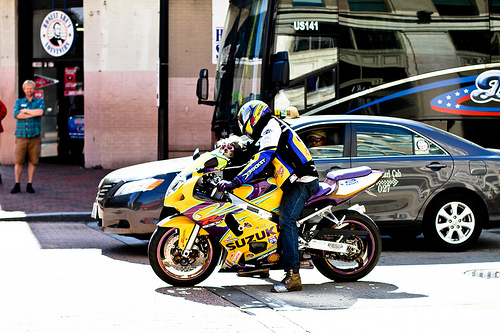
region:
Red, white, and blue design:
[433, 68, 495, 114]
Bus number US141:
[292, 15, 323, 32]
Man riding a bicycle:
[160, 103, 357, 283]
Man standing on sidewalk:
[5, 77, 47, 200]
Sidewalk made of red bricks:
[47, 169, 84, 209]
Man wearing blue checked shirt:
[11, 78, 43, 140]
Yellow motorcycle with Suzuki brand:
[166, 168, 283, 278]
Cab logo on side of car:
[376, 164, 406, 196]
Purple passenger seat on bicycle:
[328, 163, 369, 185]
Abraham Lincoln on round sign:
[37, 10, 73, 62]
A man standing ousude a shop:
[12, 73, 50, 193]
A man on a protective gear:
[225, 112, 305, 278]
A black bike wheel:
[148, 224, 215, 289]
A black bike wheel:
[325, 207, 387, 291]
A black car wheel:
[430, 187, 485, 248]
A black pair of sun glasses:
[306, 135, 328, 143]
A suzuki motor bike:
[170, 166, 395, 297]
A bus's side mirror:
[194, 66, 222, 113]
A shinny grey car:
[309, 110, 499, 242]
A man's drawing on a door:
[38, 9, 81, 59]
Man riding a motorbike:
[144, 98, 384, 290]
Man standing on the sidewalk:
[7, 75, 47, 201]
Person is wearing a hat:
[302, 125, 330, 152]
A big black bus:
[193, 37, 498, 151]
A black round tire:
[421, 188, 485, 254]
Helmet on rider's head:
[233, 95, 273, 140]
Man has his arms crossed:
[11, 76, 46, 141]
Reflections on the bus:
[236, 37, 491, 141]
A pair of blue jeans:
[276, 181, 323, 270]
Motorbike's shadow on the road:
[153, 279, 431, 315]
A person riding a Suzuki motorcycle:
[144, 95, 385, 294]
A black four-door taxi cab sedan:
[88, 112, 499, 254]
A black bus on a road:
[193, 0, 498, 157]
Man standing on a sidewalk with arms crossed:
[9, 78, 46, 197]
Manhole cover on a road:
[460, 263, 499, 284]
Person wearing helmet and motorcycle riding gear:
[215, 98, 320, 295]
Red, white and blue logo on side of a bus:
[428, 66, 499, 118]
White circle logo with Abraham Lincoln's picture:
[36, 9, 75, 58]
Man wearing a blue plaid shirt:
[14, 78, 44, 140]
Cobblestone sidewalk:
[2, 162, 108, 217]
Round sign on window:
[36, 5, 78, 61]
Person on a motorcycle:
[143, 94, 387, 296]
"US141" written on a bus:
[287, 15, 322, 35]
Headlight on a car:
[109, 173, 166, 201]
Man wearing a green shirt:
[10, 75, 48, 142]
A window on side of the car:
[352, 117, 448, 161]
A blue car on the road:
[88, 109, 498, 258]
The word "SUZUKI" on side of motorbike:
[225, 221, 282, 252]